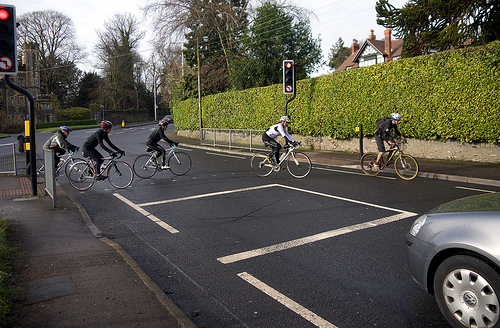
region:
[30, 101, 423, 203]
cyclists are crossing the street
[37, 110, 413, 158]
the cyclists are wearing helmets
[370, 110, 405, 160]
a man has a backpack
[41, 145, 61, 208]
fencing is along the road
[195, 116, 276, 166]
railing is on the sidewalk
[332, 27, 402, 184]
a house is behind the bushes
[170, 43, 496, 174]
a green hedge borders the sidewalk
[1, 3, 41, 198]
the signal light is red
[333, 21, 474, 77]
the house has chimneys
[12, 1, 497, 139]
tall trees are in the background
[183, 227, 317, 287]
broad white lines in street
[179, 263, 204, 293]
faint white lines in the street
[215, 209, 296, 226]
black asphalt on the street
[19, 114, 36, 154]
yellow object on side walk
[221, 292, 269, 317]
tiny white spots on street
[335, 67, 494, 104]
well manicured green shrubbery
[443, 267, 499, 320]
black and silver wheel on car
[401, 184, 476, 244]
front of passenger car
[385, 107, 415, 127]
silver helmet on man's head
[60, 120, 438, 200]
bikers riding in the street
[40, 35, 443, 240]
bicyclists riding across the street.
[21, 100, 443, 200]
several bicyclists riding across the street.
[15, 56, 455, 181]
group of bicyclists riding across the street.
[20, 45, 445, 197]
multiple bicyclists riding across the street.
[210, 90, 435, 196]
two people riding bicycles across street.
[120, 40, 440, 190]
three people riding bicycles across street.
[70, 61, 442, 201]
four people riding bicycles across street.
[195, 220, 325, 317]
white lines in roadway.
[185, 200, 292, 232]
cement pavement area in view.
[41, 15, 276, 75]
group of green trees.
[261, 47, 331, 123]
red stop light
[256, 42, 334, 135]
a stop light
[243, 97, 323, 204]
a person riding a bike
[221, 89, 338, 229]
a person wearing a white shirt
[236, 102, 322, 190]
a person wearing a helmet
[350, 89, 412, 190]
a person wearing a black shirt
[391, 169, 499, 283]
a silver vehicle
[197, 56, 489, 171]
green bushes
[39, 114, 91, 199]
a person wearing a blue helmet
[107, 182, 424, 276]
white lines on the road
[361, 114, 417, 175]
a bicyclist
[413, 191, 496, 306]
the front of a silver car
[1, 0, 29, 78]
A traffic light that has turned red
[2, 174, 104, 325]
A sidewalk next to a road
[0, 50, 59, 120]
An old stone building.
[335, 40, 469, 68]
A building's roof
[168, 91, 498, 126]
a hedge next to a sidewalk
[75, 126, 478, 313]
A street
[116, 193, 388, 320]
Paint marks on the road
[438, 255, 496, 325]
The left front tire of a car